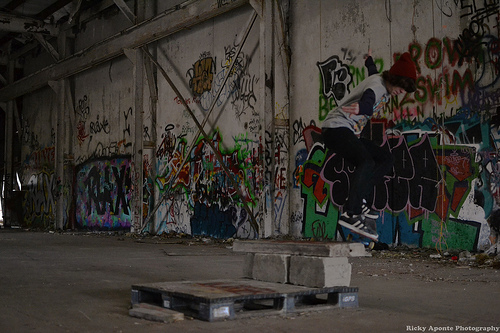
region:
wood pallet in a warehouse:
[130, 280, 357, 320]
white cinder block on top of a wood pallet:
[287, 253, 351, 288]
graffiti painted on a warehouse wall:
[0, 24, 497, 264]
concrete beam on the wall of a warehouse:
[0, 0, 247, 97]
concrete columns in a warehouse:
[127, 47, 145, 234]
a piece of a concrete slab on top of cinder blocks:
[230, 237, 365, 256]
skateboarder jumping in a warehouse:
[322, 52, 417, 239]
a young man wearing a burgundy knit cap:
[390, 51, 418, 81]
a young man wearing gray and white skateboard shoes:
[337, 212, 377, 242]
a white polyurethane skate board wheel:
[367, 240, 374, 250]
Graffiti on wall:
[9, 27, 497, 255]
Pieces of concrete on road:
[226, 228, 392, 294]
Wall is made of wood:
[0, 5, 498, 249]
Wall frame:
[8, 5, 296, 237]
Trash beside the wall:
[21, 205, 491, 255]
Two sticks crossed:
[143, 7, 270, 242]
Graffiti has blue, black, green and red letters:
[289, 20, 493, 264]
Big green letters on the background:
[291, 126, 497, 261]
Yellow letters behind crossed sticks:
[181, 50, 220, 99]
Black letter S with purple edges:
[317, 154, 356, 213]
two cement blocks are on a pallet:
[252, 245, 349, 284]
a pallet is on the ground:
[134, 277, 368, 319]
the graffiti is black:
[322, 123, 444, 209]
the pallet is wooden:
[127, 270, 367, 320]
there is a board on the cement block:
[225, 227, 375, 261]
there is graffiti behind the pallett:
[279, 5, 499, 266]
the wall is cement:
[2, 2, 497, 264]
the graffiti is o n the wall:
[151, 120, 286, 233]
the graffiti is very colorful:
[67, 147, 143, 234]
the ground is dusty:
[0, 228, 499, 331]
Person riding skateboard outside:
[293, 27, 456, 264]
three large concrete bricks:
[219, 220, 374, 293]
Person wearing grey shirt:
[282, 28, 453, 267]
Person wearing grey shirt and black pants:
[297, 26, 435, 283]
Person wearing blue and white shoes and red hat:
[290, 35, 450, 275]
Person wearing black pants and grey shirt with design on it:
[267, 20, 456, 267]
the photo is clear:
[5, 6, 496, 331]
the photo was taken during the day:
[1, 2, 496, 330]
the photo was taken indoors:
[10, 0, 499, 331]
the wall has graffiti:
[16, 95, 499, 245]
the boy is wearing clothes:
[308, 30, 448, 252]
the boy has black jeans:
[322, 108, 435, 232]